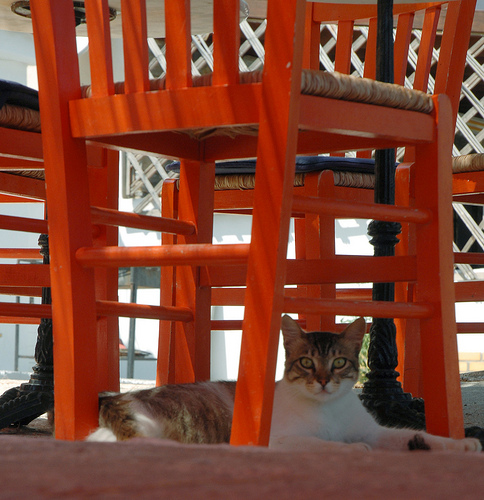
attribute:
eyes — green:
[299, 357, 348, 369]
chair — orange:
[27, 2, 477, 447]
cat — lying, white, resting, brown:
[85, 313, 482, 454]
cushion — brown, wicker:
[77, 66, 435, 108]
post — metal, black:
[0, 0, 484, 451]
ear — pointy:
[340, 316, 366, 355]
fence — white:
[130, 15, 483, 283]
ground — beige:
[0, 369, 484, 499]